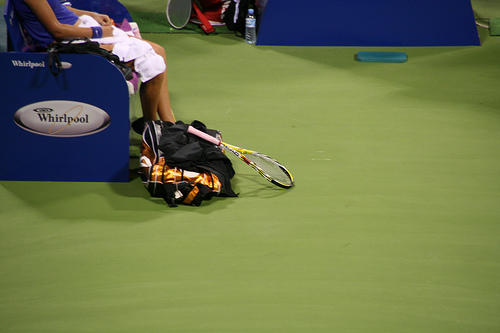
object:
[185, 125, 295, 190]
racket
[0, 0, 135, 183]
bench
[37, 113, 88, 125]
whirlpool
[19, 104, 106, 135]
ad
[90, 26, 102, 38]
wrist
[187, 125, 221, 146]
handle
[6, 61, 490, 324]
carpeting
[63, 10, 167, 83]
towel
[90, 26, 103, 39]
blue wristband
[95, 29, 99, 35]
white symbol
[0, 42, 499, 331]
ground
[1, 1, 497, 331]
floor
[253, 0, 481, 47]
bench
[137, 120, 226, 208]
bag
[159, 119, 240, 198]
gear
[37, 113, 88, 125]
letter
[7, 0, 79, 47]
shirt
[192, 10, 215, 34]
strap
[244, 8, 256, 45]
bottle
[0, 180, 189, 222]
shadow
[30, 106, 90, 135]
symbol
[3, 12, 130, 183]
seating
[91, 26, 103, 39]
wrist band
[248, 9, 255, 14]
lid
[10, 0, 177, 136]
person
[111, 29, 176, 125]
legs crossed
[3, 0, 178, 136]
people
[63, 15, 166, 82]
sweat